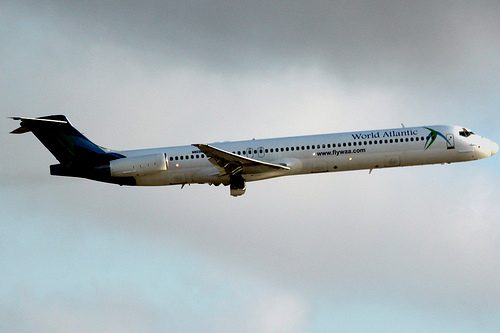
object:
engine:
[109, 152, 168, 178]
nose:
[474, 134, 499, 158]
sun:
[439, 91, 468, 145]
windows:
[294, 138, 423, 150]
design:
[422, 125, 455, 151]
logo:
[428, 125, 450, 150]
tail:
[6, 109, 132, 192]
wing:
[180, 137, 283, 188]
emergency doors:
[257, 147, 264, 158]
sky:
[3, 1, 496, 331]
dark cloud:
[48, 2, 498, 86]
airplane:
[5, 114, 499, 199]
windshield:
[458, 129, 474, 136]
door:
[446, 134, 454, 150]